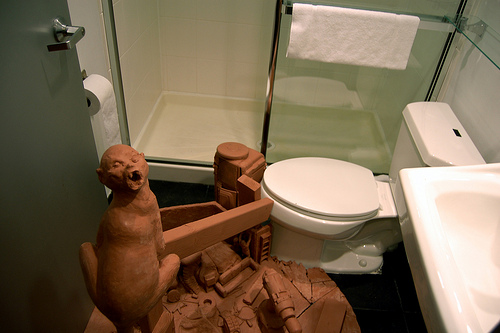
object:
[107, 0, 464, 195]
shower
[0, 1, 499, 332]
bathroom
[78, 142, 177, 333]
monkey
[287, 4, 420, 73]
towel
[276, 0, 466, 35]
hanger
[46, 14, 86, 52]
handle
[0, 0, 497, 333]
room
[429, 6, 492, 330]
wall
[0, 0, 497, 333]
image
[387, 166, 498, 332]
sink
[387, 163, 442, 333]
edge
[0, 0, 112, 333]
door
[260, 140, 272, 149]
drain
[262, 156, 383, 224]
lid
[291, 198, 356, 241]
edge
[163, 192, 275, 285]
part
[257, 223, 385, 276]
side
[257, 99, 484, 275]
toilet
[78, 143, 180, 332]
cat creature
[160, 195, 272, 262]
beam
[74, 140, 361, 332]
carving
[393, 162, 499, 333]
bathroom sink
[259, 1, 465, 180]
shower door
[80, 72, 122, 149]
toilet paper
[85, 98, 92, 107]
roll